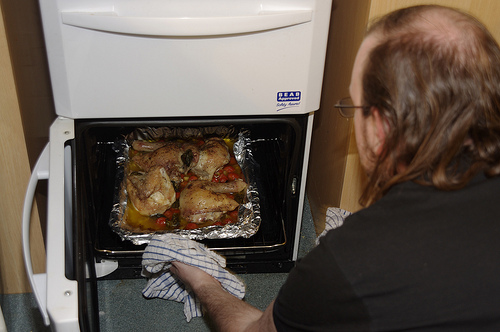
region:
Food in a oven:
[116, 133, 297, 256]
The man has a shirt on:
[266, 22, 497, 325]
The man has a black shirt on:
[253, 131, 490, 323]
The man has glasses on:
[330, 13, 486, 164]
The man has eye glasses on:
[324, 3, 479, 205]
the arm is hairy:
[202, 285, 262, 322]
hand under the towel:
[149, 245, 238, 297]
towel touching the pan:
[129, 237, 240, 301]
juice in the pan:
[124, 206, 158, 232]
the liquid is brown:
[127, 207, 158, 242]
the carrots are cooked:
[181, 171, 241, 184]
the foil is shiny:
[231, 197, 254, 240]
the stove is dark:
[87, 129, 120, 201]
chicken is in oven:
[92, 109, 245, 243]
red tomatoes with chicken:
[97, 124, 240, 241]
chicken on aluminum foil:
[102, 136, 264, 264]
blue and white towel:
[156, 214, 266, 306]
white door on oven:
[15, 123, 79, 330]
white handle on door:
[18, 155, 47, 284]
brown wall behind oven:
[342, 14, 358, 56]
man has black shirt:
[324, 204, 441, 329]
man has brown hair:
[368, 46, 498, 208]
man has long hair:
[361, 1, 493, 208]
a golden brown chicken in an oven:
[124, 167, 174, 214]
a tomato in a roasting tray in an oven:
[157, 217, 165, 227]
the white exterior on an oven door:
[24, 119, 78, 329]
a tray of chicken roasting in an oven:
[110, 125, 266, 237]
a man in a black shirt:
[164, 2, 498, 329]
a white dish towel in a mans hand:
[140, 232, 247, 317]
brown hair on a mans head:
[360, 4, 497, 204]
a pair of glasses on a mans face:
[336, 95, 369, 116]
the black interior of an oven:
[73, 112, 310, 279]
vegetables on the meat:
[177, 156, 242, 187]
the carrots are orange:
[212, 165, 234, 182]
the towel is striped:
[150, 238, 223, 313]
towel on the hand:
[150, 246, 233, 305]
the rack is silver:
[92, 230, 156, 262]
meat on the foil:
[135, 134, 235, 241]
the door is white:
[27, 123, 72, 315]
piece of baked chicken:
[179, 187, 238, 222]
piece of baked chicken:
[186, 177, 248, 193]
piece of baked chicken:
[189, 138, 229, 179]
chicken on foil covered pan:
[104, 124, 264, 247]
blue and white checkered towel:
[137, 229, 248, 328]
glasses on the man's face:
[307, 78, 386, 146]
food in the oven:
[98, 115, 263, 238]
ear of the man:
[346, 93, 413, 170]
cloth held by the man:
[120, 227, 240, 319]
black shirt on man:
[261, 150, 498, 311]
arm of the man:
[166, 258, 274, 328]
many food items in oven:
[98, 129, 251, 237]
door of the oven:
[1, 122, 109, 285]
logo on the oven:
[258, 77, 308, 129]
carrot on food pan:
[153, 215, 166, 224]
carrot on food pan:
[183, 221, 196, 230]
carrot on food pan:
[161, 208, 171, 217]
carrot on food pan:
[228, 207, 239, 217]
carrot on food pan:
[216, 170, 226, 181]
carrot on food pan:
[226, 172, 237, 181]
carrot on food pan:
[221, 163, 233, 172]